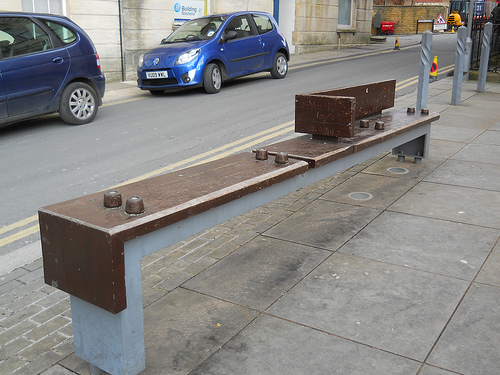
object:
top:
[36, 106, 439, 314]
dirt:
[0, 98, 59, 127]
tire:
[204, 63, 222, 93]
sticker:
[206, 30, 215, 37]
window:
[161, 15, 229, 44]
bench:
[36, 78, 440, 375]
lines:
[0, 120, 294, 247]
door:
[223, 13, 264, 75]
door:
[0, 13, 70, 117]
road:
[0, 33, 500, 375]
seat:
[294, 78, 397, 142]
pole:
[416, 29, 433, 111]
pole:
[451, 25, 468, 106]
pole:
[476, 21, 493, 93]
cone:
[429, 55, 438, 79]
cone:
[393, 35, 400, 50]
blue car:
[0, 10, 106, 127]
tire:
[58, 82, 98, 125]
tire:
[270, 52, 288, 79]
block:
[37, 76, 499, 375]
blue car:
[136, 10, 291, 95]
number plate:
[146, 71, 169, 80]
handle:
[53, 57, 62, 62]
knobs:
[104, 189, 145, 214]